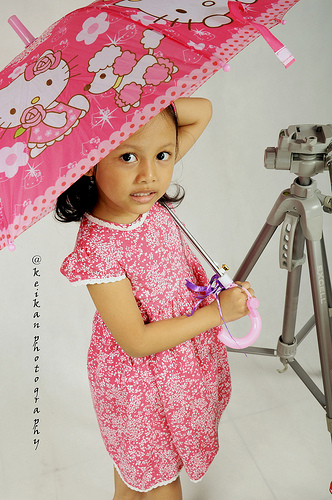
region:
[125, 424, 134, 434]
a pink flower on a dress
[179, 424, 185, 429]
a pink flower on a dress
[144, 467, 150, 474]
a pink flower on a dress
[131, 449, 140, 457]
a pink flower on a dress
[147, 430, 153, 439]
a pink flower on a dress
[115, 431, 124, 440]
a pink flower on a dress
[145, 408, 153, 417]
a pink flower on a dress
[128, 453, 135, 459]
a pink flower on a dress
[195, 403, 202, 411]
a pink flower on a dress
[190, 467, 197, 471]
a pink flower on a dress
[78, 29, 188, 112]
pink and white poodle with yellow collar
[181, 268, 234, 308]
purple ribbon tied to umbrella handle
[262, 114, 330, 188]
top of tripod camera holder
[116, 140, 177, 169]
little girl big brown eyes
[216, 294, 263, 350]
pink umbrella handle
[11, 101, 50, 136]
pink rose with green leaf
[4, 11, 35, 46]
pink tip of an umbrella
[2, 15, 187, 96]
pink umbrella with colorful animals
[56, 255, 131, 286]
pink and white sleeve with white scalloped trim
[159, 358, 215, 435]
pink dress with multi white flowers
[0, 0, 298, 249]
pink and white hello kitty umbrella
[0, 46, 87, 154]
hello kitten cartoon character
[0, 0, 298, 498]
young girl holding hello kitty umbrella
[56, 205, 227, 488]
small female child wearing a pink and white dress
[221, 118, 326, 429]
gray metal tripod with three legs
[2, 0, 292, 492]
little girl posing for a picture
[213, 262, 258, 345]
handle of umbrella in girl's hand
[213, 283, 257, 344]
pink handle to the hello kitty umbrella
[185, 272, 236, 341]
purple ribbon on girl's dress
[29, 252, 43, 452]
@keikan photography watermark on picture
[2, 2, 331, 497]
little girl posing with umbrella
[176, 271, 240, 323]
purple ribbon tied on girls wrist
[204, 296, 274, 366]
pink handle of an umbrella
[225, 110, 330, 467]
silver camera tripod on the side of girl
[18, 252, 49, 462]
copyright of a photographer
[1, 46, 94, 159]
Hello Kitty on umbrella image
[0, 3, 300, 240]
pink Hello Kitty umbrella little girl is holding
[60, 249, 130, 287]
sleeve of a pink dress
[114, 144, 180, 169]
eyes of a little girl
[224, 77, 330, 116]
white backdrop behind the girl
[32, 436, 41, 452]
the black letter Y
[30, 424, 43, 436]
the black letter H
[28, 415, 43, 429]
the black letter P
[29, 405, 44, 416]
the black letter A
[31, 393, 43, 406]
the black letter R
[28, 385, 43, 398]
the black letter G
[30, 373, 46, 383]
the black letter O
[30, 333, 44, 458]
the word photography in black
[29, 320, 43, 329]
the black letter N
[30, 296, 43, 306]
the black letter K